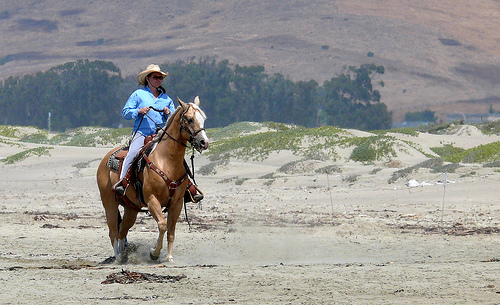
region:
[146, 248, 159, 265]
Hoof of tan horse.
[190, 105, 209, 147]
White shape on tan horses face.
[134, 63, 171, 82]
Tan cowboy hat on woman.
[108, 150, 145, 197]
Red stirrups on side of horse.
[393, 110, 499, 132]
Body of water in the distance.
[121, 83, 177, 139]
Blue shirt being worn by a woman.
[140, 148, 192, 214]
Red harness on horse.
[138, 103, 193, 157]
Woman holding onto horses reigns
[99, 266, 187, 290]
Brown pile on sand.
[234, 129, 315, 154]
Greenery growing on sand dunes.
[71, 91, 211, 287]
brown horse running on beach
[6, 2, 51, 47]
white clouds in blue sky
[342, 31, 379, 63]
white clouds in blue sky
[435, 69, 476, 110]
white clouds in blue sky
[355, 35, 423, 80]
white clouds in blue sky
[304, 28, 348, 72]
white clouds in blue sky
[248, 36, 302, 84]
white clouds in blue sky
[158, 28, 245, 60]
white clouds in blue sky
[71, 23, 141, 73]
white clouds in blue sky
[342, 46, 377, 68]
white clouds in blue sky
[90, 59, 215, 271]
man in blue shirt riding horse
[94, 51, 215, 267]
man wearing cowboy hat riding horse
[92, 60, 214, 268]
tan and white horse with rider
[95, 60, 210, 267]
horse with saddle and bridle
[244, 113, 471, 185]
grass on low sand dunes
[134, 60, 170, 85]
straw cowboy hat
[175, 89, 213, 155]
face of horse with ears back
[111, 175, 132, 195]
foot in saddle stirrup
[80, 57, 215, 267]
horse riding in sandy soil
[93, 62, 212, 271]
horse and rider with trees in background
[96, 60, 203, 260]
Woman on a horse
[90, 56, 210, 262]
Woman is on a horse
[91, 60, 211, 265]
Woman riding a horse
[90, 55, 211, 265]
Woman is riding a horse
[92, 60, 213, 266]
Woman on a brown horse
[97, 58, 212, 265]
Woman is on a brown horse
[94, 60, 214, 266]
Woman riding a brown horse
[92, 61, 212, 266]
Woman is riding a brown horse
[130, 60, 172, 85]
Woman wearing a hat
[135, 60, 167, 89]
Woman is wearing a hat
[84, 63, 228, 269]
a beautiful palomino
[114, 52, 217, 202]
the lady is wearing a blue shirt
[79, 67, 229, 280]
the horse's tack is is lovely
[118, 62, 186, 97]
the lady is wearing a straw hat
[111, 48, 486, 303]
they appear to be riding in the high dessert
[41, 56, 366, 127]
a thicket of trees in the background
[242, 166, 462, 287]
the landscape appears very barren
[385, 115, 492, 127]
a stream is in the background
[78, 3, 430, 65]
the mountain appears to be without trees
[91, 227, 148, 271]
the horse has two white "socks" on his rear feet